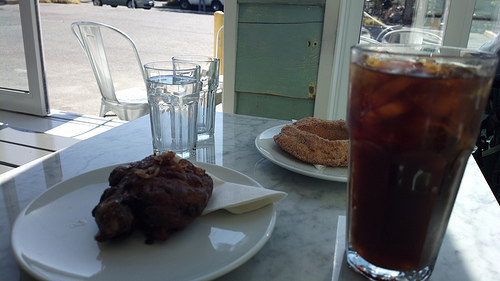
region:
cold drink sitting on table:
[347, 40, 472, 260]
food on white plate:
[87, 171, 221, 242]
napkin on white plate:
[189, 167, 294, 231]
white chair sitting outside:
[77, 32, 127, 108]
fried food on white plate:
[278, 110, 344, 185]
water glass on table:
[150, 55, 197, 153]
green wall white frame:
[220, 16, 347, 102]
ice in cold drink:
[369, 53, 470, 90]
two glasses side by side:
[139, 57, 226, 158]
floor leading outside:
[18, 112, 105, 142]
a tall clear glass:
[345, 40, 498, 279]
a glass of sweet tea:
[346, 41, 498, 278]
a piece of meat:
[92, 150, 213, 244]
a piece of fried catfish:
[275, 116, 350, 171]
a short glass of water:
[144, 61, 199, 152]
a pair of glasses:
[145, 53, 220, 155]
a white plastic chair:
[69, 19, 151, 120]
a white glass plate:
[12, 157, 274, 279]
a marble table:
[0, 103, 498, 278]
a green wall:
[235, 0, 326, 121]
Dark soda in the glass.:
[352, 58, 466, 267]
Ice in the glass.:
[377, 60, 454, 119]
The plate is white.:
[76, 247, 153, 276]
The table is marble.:
[280, 231, 332, 274]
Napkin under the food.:
[196, 166, 228, 213]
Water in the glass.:
[150, 81, 201, 149]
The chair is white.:
[82, 73, 156, 111]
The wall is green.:
[241, 38, 293, 98]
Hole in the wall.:
[292, 80, 326, 106]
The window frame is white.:
[324, 24, 353, 85]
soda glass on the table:
[345, 43, 495, 277]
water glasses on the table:
[137, 52, 232, 152]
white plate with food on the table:
[3, 142, 283, 279]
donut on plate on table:
[278, 115, 353, 159]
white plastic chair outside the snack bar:
[68, 16, 192, 116]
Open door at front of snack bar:
[3, 0, 56, 117]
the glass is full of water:
[136, 51, 201, 161]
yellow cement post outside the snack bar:
[212, 9, 225, 78]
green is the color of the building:
[233, 22, 315, 100]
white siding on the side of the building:
[321, 3, 346, 118]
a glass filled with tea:
[334, 42, 496, 279]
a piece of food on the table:
[93, 155, 208, 246]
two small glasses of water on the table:
[146, 53, 218, 153]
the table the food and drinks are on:
[1, 95, 499, 278]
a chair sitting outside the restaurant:
[64, 21, 152, 118]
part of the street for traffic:
[6, 2, 216, 102]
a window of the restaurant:
[334, 0, 499, 150]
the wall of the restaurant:
[3, 2, 498, 182]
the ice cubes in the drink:
[343, 53, 476, 150]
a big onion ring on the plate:
[262, 115, 352, 161]